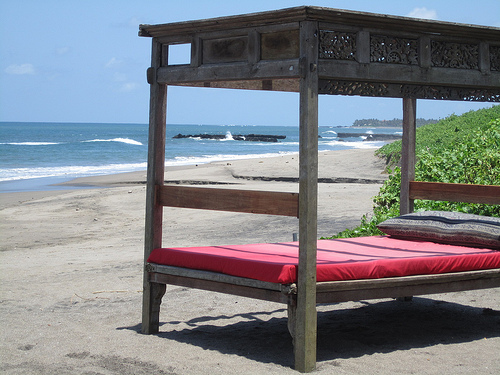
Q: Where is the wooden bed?
A: On the beach.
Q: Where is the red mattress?
A: On the wooden frame.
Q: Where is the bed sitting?
A: On a beach.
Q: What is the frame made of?
A: Wood.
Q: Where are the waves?
A: In the ocean.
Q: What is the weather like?
A: Clear.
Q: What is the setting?
A: A beach.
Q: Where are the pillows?
A: On the bed.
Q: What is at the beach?
A: Bed.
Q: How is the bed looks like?
A: Pretty good.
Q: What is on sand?
A: Bed.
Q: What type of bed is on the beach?
A: Wood.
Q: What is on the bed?
A: Red sheet.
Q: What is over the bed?
A: Canopy.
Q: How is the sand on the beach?
A: White.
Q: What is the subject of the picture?
A: Bed.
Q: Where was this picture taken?
A: Beach.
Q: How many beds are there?
A: One.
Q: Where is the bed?
A: On the beach.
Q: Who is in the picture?
A: No one.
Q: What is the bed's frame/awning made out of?
A: Wood.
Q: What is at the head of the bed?
A: Pillow.